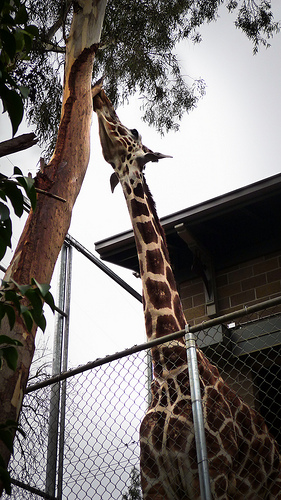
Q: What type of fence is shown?
A: Chain link fence.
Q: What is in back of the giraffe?
A: A brick building.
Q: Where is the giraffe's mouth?
A: The tree bark.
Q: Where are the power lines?
A: Behind the building.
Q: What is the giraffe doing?
A: Eating.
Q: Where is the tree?
A: In front of the giraffe.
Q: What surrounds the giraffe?
A: A metal fence.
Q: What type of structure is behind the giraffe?
A: A brick building.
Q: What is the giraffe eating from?
A: A tree.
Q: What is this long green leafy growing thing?
A: Tree.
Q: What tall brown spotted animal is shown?
A: Giraffe.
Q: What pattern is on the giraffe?
A: Spots.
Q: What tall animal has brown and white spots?
A: Giraffe.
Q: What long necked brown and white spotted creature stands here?
A: Giraffe.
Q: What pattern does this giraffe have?
A: Spots.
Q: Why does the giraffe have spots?
A: Genetics.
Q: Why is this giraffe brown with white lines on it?
A: Genetics.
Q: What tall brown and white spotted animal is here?
A: Giraffe.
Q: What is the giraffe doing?
A: Eating.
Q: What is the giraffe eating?
A: Leaves.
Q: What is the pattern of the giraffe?
A: Spotted.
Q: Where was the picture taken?
A: Zoo.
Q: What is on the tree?
A: Leaves.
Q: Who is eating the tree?
A: A giraffe.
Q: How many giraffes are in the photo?
A: 1.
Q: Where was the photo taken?
A: A zoo.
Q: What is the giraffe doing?
A: Eating.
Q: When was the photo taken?
A: Daytime.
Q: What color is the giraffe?
A: Brown and tan.